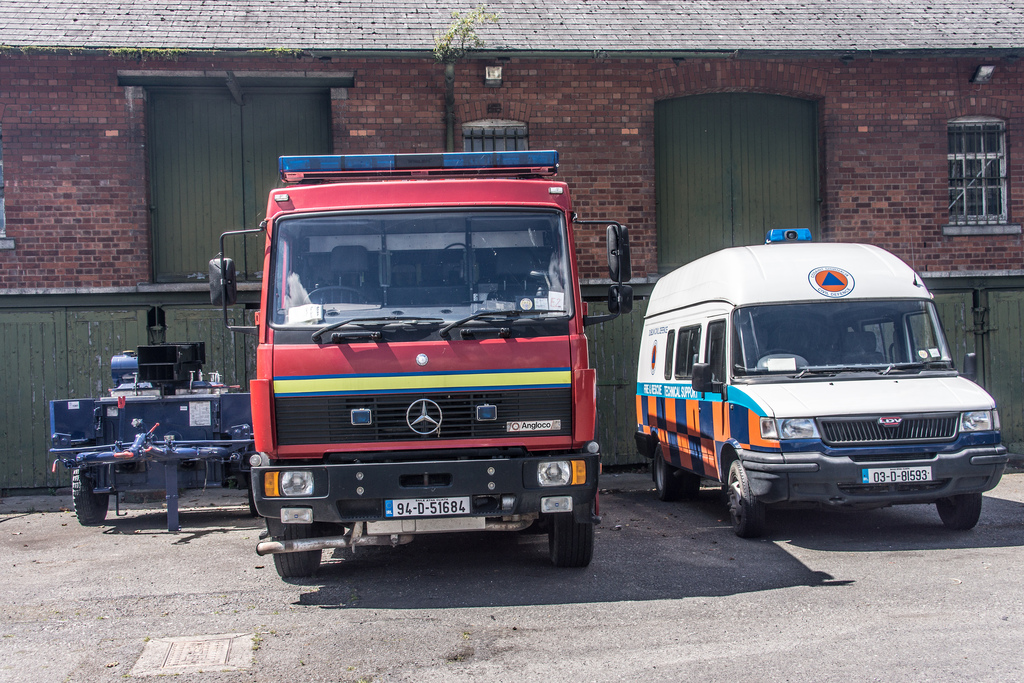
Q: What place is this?
A: It is a pavement.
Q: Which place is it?
A: It is a pavement.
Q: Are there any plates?
A: Yes, there is a plate.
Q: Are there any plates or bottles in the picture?
A: Yes, there is a plate.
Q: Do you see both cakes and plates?
A: No, there is a plate but no cakes.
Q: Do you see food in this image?
A: No, there is no food.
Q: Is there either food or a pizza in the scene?
A: No, there are no food or pizzas.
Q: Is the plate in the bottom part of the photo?
A: Yes, the plate is in the bottom of the image.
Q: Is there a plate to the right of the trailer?
A: Yes, there is a plate to the right of the trailer.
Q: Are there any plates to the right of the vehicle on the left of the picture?
A: Yes, there is a plate to the right of the trailer.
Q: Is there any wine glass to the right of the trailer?
A: No, there is a plate to the right of the trailer.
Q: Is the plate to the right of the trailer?
A: Yes, the plate is to the right of the trailer.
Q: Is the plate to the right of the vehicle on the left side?
A: Yes, the plate is to the right of the trailer.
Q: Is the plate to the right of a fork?
A: No, the plate is to the right of the trailer.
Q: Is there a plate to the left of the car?
A: Yes, there is a plate to the left of the car.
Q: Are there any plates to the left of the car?
A: Yes, there is a plate to the left of the car.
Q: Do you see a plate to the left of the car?
A: Yes, there is a plate to the left of the car.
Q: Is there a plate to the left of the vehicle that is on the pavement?
A: Yes, there is a plate to the left of the car.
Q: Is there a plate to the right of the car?
A: No, the plate is to the left of the car.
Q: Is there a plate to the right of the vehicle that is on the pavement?
A: No, the plate is to the left of the car.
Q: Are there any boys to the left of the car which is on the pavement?
A: No, there is a plate to the left of the car.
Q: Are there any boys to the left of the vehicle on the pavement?
A: No, there is a plate to the left of the car.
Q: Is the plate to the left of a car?
A: Yes, the plate is to the left of a car.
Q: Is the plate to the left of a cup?
A: No, the plate is to the left of a car.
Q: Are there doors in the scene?
A: Yes, there are doors.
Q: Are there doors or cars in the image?
A: Yes, there are doors.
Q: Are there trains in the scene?
A: No, there are no trains.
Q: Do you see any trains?
A: No, there are no trains.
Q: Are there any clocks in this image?
A: No, there are no clocks.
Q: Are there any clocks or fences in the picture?
A: No, there are no clocks or fences.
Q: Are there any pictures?
A: No, there are no pictures.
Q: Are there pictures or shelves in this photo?
A: No, there are no pictures or shelves.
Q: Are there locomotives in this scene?
A: No, there are no locomotives.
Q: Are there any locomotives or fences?
A: No, there are no locomotives or fences.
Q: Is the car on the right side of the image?
A: Yes, the car is on the right of the image.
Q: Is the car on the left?
A: No, the car is on the right of the image.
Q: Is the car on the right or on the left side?
A: The car is on the right of the image.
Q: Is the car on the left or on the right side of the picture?
A: The car is on the right of the image.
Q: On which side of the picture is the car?
A: The car is on the right of the image.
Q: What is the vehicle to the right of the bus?
A: The vehicle is a car.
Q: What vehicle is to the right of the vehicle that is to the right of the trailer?
A: The vehicle is a car.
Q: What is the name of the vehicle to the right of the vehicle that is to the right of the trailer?
A: The vehicle is a car.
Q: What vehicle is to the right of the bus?
A: The vehicle is a car.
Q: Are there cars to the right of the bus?
A: Yes, there is a car to the right of the bus.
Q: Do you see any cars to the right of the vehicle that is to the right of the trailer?
A: Yes, there is a car to the right of the bus.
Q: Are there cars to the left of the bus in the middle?
A: No, the car is to the right of the bus.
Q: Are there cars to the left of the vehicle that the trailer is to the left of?
A: No, the car is to the right of the bus.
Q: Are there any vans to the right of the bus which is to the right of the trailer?
A: No, there is a car to the right of the bus.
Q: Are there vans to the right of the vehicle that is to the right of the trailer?
A: No, there is a car to the right of the bus.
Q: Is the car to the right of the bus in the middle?
A: Yes, the car is to the right of the bus.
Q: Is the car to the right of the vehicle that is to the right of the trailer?
A: Yes, the car is to the right of the bus.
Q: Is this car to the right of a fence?
A: No, the car is to the right of the bus.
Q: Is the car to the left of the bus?
A: No, the car is to the right of the bus.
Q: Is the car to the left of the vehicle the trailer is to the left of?
A: No, the car is to the right of the bus.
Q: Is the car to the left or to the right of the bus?
A: The car is to the right of the bus.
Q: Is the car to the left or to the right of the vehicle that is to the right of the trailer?
A: The car is to the right of the bus.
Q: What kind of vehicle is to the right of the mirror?
A: The vehicle is a car.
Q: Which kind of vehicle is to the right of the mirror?
A: The vehicle is a car.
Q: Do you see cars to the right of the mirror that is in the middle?
A: Yes, there is a car to the right of the mirror.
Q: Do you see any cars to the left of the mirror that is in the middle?
A: No, the car is to the right of the mirror.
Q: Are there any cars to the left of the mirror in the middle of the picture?
A: No, the car is to the right of the mirror.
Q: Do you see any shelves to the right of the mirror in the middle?
A: No, there is a car to the right of the mirror.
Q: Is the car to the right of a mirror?
A: Yes, the car is to the right of a mirror.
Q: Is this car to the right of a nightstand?
A: No, the car is to the right of a mirror.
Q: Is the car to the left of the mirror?
A: No, the car is to the right of the mirror.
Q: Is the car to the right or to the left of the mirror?
A: The car is to the right of the mirror.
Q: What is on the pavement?
A: The car is on the pavement.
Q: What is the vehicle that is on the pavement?
A: The vehicle is a car.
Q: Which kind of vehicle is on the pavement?
A: The vehicle is a car.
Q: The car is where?
A: The car is on the pavement.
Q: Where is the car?
A: The car is on the pavement.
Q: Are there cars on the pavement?
A: Yes, there is a car on the pavement.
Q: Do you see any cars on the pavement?
A: Yes, there is a car on the pavement.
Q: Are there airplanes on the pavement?
A: No, there is a car on the pavement.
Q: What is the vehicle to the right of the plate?
A: The vehicle is a car.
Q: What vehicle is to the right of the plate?
A: The vehicle is a car.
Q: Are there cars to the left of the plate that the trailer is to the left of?
A: No, the car is to the right of the plate.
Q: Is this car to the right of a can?
A: No, the car is to the right of the plate.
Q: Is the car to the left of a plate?
A: No, the car is to the right of a plate.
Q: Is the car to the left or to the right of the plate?
A: The car is to the right of the plate.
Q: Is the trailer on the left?
A: Yes, the trailer is on the left of the image.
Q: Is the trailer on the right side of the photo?
A: No, the trailer is on the left of the image.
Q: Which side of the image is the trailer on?
A: The trailer is on the left of the image.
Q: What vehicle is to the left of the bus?
A: The vehicle is a trailer.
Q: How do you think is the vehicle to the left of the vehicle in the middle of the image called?
A: The vehicle is a trailer.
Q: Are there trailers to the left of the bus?
A: Yes, there is a trailer to the left of the bus.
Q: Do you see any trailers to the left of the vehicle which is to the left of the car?
A: Yes, there is a trailer to the left of the bus.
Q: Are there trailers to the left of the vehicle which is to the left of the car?
A: Yes, there is a trailer to the left of the bus.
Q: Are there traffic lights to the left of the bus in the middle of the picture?
A: No, there is a trailer to the left of the bus.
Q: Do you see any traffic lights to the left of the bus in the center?
A: No, there is a trailer to the left of the bus.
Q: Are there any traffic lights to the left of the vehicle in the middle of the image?
A: No, there is a trailer to the left of the bus.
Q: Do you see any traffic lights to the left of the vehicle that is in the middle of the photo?
A: No, there is a trailer to the left of the bus.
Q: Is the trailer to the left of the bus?
A: Yes, the trailer is to the left of the bus.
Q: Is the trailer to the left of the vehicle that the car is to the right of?
A: Yes, the trailer is to the left of the bus.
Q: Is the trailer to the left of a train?
A: No, the trailer is to the left of the bus.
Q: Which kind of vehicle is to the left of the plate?
A: The vehicle is a trailer.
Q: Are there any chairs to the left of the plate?
A: No, there is a trailer to the left of the plate.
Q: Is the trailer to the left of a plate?
A: Yes, the trailer is to the left of a plate.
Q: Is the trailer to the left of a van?
A: No, the trailer is to the left of a plate.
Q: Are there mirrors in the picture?
A: Yes, there is a mirror.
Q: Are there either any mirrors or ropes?
A: Yes, there is a mirror.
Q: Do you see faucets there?
A: No, there are no faucets.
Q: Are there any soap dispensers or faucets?
A: No, there are no faucets or soap dispensers.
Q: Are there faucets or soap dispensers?
A: No, there are no faucets or soap dispensers.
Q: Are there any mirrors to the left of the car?
A: Yes, there is a mirror to the left of the car.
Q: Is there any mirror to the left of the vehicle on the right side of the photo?
A: Yes, there is a mirror to the left of the car.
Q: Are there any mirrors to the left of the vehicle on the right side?
A: Yes, there is a mirror to the left of the car.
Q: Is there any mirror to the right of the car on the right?
A: No, the mirror is to the left of the car.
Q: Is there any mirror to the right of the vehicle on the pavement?
A: No, the mirror is to the left of the car.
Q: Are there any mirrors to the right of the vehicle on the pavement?
A: No, the mirror is to the left of the car.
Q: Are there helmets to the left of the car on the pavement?
A: No, there is a mirror to the left of the car.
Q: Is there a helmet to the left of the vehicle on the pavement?
A: No, there is a mirror to the left of the car.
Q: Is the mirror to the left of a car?
A: Yes, the mirror is to the left of a car.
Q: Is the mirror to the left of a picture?
A: No, the mirror is to the left of a car.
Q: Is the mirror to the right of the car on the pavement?
A: No, the mirror is to the left of the car.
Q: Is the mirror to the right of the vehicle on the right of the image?
A: No, the mirror is to the left of the car.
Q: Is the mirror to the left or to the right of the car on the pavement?
A: The mirror is to the left of the car.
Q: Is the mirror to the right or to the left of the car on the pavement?
A: The mirror is to the left of the car.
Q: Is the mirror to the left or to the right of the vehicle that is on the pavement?
A: The mirror is to the left of the car.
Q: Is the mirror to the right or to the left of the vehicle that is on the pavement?
A: The mirror is to the left of the car.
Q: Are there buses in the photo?
A: Yes, there is a bus.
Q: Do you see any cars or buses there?
A: Yes, there is a bus.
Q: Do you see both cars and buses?
A: Yes, there are both a bus and a car.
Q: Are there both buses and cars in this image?
A: Yes, there are both a bus and a car.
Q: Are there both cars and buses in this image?
A: Yes, there are both a bus and a car.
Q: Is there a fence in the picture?
A: No, there are no fences.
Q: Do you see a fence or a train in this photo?
A: No, there are no fences or trains.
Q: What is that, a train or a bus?
A: That is a bus.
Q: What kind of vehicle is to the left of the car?
A: The vehicle is a bus.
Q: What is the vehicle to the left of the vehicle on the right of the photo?
A: The vehicle is a bus.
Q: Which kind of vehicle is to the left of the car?
A: The vehicle is a bus.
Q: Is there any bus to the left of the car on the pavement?
A: Yes, there is a bus to the left of the car.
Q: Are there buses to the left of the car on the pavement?
A: Yes, there is a bus to the left of the car.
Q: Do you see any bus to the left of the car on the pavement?
A: Yes, there is a bus to the left of the car.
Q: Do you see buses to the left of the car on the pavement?
A: Yes, there is a bus to the left of the car.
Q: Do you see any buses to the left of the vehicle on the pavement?
A: Yes, there is a bus to the left of the car.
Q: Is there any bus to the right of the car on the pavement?
A: No, the bus is to the left of the car.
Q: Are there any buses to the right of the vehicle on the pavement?
A: No, the bus is to the left of the car.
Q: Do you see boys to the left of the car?
A: No, there is a bus to the left of the car.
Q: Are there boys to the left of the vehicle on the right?
A: No, there is a bus to the left of the car.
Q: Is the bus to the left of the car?
A: Yes, the bus is to the left of the car.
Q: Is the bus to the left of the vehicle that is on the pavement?
A: Yes, the bus is to the left of the car.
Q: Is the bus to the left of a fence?
A: No, the bus is to the left of the car.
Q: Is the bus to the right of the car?
A: No, the bus is to the left of the car.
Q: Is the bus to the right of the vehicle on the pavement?
A: No, the bus is to the left of the car.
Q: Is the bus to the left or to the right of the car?
A: The bus is to the left of the car.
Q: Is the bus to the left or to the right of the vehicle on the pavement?
A: The bus is to the left of the car.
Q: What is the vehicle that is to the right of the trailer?
A: The vehicle is a bus.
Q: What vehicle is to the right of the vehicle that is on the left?
A: The vehicle is a bus.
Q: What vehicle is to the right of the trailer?
A: The vehicle is a bus.